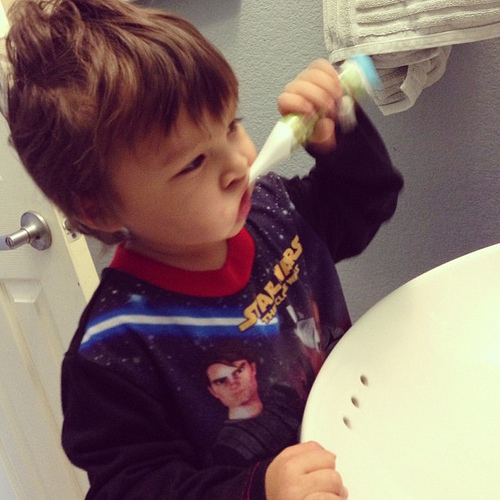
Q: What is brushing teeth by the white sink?
A: The little boy.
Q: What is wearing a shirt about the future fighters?
A: The boy.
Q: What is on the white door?
A: The silver knob.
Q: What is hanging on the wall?
A: Edges of the gray towel.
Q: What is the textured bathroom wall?
A: Grey.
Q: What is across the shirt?
A: Blue and white stripe.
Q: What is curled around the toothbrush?
A: The hand.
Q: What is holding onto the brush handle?
A: The boy.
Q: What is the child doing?
A: Brushing his teeth.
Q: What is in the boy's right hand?
A: A toothbrush.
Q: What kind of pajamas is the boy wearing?
A: Star Wars pajamas.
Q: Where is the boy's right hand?
A: On the sink.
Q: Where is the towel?
A: On the wall to the right of the boy.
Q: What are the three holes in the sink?
A: Drain holes.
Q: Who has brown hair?
A: The boy.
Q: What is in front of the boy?
A: A sink.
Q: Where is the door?
A: Behind the boy.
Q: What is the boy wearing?
A: Star Wars pajamas.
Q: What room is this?
A: Bathroom.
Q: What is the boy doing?
A: Brushing his teeth.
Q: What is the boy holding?
A: A toothbrush.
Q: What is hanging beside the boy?
A: A towel.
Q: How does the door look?
A: Open.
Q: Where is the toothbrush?
A: In his mouth.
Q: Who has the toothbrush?
A: The boy.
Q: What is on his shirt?
A: Star Wars.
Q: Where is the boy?
A: Bathroom.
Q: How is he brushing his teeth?
A: Toothbrush.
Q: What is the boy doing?
A: Brushing his teeth.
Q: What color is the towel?
A: Cream.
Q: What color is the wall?
A: Grey.